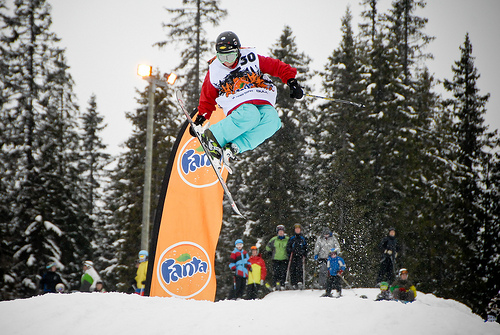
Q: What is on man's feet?
A: Skis.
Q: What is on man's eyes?
A: Goggles.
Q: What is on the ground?
A: Snow.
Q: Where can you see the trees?
A: Behind the people.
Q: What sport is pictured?
A: Snowboarding.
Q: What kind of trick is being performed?
A: A jump.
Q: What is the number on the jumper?
A: 30.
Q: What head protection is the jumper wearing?
A: A helmet.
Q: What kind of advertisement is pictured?
A: A banner.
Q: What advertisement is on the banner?
A: Fanta.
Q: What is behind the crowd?
A: Pine trees.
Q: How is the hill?
A: Snow covered.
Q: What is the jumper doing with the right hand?
A: Holding the snowboard.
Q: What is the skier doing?
A: Performing a trick.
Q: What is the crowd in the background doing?
A: Watching the skier performing a trick.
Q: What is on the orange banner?
A: The logo for Fanta.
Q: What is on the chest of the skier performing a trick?
A: A racing bib.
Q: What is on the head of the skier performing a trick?
A: A helmet.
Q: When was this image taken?
A: In the afternoon.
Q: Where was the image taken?
A: At a skiing competition.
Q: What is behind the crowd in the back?
A: Large pine trees.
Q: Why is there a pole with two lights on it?
A: To illuminate the area when it's dark.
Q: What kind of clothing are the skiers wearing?
A: Snow pants and jackets.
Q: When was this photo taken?
A: In the winter.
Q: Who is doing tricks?
A: Number 30.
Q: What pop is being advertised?
A: Fanta.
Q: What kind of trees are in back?
A: Pine trees.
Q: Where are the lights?
A: Behind the Fanta sign.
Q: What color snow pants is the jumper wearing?
A: Turquoise.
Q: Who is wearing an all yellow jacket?
A: The person by the light pole.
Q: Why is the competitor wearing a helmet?
A: For safety.